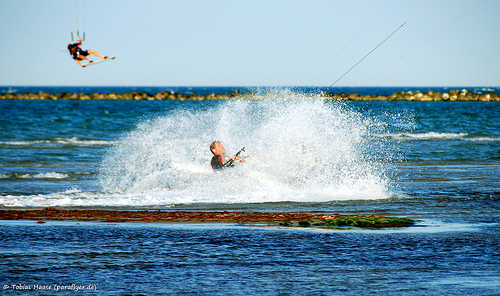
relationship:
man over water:
[63, 33, 116, 70] [1, 86, 498, 292]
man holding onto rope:
[208, 136, 248, 173] [236, 2, 436, 155]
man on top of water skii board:
[63, 33, 116, 70] [78, 53, 118, 70]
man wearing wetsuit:
[208, 136, 248, 173] [211, 156, 234, 173]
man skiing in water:
[208, 136, 248, 173] [1, 86, 498, 292]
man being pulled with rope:
[208, 136, 248, 173] [236, 2, 436, 155]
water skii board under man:
[78, 53, 118, 70] [63, 33, 116, 70]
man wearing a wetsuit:
[208, 136, 248, 173] [211, 156, 234, 173]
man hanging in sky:
[63, 33, 116, 70] [1, 0, 499, 86]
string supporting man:
[70, 0, 83, 38] [63, 33, 116, 70]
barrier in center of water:
[0, 85, 500, 109] [1, 86, 498, 292]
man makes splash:
[208, 136, 248, 173] [94, 84, 423, 209]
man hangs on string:
[63, 33, 116, 70] [70, 0, 83, 38]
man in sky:
[63, 33, 116, 70] [1, 0, 499, 86]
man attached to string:
[63, 33, 116, 70] [70, 0, 83, 38]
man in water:
[208, 136, 248, 173] [1, 86, 498, 292]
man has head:
[208, 136, 248, 173] [208, 139, 227, 157]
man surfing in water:
[208, 136, 248, 173] [1, 86, 498, 292]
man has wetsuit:
[208, 136, 248, 173] [211, 156, 234, 173]